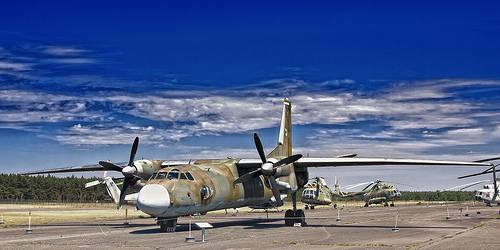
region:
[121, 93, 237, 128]
menacing storm clouds overhead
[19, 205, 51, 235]
small white pole on the ground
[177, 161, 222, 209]
rust on the plane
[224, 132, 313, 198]
black blades on the wing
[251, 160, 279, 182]
white cone on nose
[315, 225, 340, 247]
faint line on the gray ground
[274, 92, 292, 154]
white paint on the wing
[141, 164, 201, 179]
windows on the front of the plane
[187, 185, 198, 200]
small hole in plane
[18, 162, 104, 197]
large forest of green trees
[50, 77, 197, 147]
white clouds on a blue sky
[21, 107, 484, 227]
rusty airplane on a landing strip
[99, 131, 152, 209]
four armed propeller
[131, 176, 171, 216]
pointy white cap on nose of plane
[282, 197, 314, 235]
wheels on a plane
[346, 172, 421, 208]
rusty airplane on the tarmac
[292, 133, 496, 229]
several old planes waiting on the asphalt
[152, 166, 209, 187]
cockpit windows on plane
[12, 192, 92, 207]
small fence along the runway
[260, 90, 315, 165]
dirty tail fin on airplane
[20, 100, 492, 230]
an old rusty propellar driven plane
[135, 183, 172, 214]
the nose of a prop plane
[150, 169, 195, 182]
the windshield of a prop plane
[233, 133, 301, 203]
the left propellar of a plane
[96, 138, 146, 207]
the right propellar of a plane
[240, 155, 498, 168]
a plane's left wing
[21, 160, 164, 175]
a plane's right lane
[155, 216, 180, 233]
a plane's front wheel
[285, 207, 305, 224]
a plane's left rear wheel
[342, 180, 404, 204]
a helicopter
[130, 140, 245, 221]
rusty old airplane on the tarmac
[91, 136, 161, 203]
propeller on an airplane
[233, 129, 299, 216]
propeller on an airplane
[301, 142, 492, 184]
white airplane wing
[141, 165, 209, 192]
cockpit windows on a plane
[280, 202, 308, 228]
landing wheels on a plane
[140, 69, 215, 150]
white clouds in the sky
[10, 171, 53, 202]
forest near the tarmac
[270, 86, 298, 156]
tail fin on an airplane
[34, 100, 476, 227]
planes on a tarmac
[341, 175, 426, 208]
Discolored helicopter in background.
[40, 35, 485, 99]
Beautiful partially cloudy blue sky.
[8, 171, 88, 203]
Green trees line background.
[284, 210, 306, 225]
Set of wheels on airplane.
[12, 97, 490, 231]
Discolored airplane on runway.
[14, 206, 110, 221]
Field with dried out grass.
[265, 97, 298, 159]
Fin of airplane.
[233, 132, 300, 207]
Airplane engine fan blades.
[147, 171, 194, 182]
Windows to airplane cockpit.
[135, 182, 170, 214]
White nose tip of airplane.